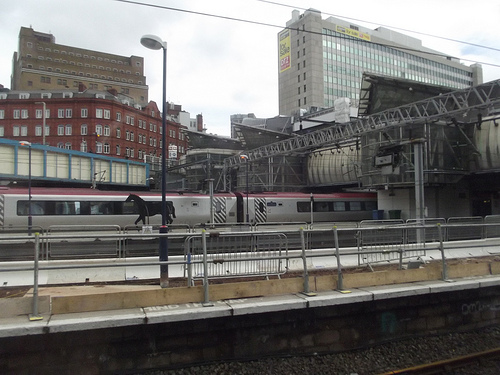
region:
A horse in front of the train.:
[123, 186, 183, 232]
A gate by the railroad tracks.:
[181, 231, 293, 289]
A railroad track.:
[270, 327, 497, 372]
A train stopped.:
[5, 184, 381, 229]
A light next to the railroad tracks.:
[120, 27, 206, 306]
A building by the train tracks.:
[5, 130, 157, 193]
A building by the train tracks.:
[10, 16, 158, 93]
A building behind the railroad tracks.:
[270, 17, 497, 147]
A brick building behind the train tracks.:
[2, 84, 211, 174]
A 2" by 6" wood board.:
[50, 266, 316, 317]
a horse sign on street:
[119, 178, 180, 226]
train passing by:
[3, 172, 390, 227]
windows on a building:
[25, 107, 103, 120]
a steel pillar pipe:
[399, 118, 436, 265]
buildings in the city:
[266, 6, 497, 134]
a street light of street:
[109, 22, 204, 294]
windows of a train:
[292, 185, 381, 218]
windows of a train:
[4, 187, 183, 222]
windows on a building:
[330, 40, 398, 72]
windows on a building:
[290, 20, 315, 113]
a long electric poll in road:
[135, 23, 191, 313]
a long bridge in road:
[43, 215, 493, 304]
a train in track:
[43, 175, 377, 227]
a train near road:
[23, 163, 390, 229]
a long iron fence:
[55, 231, 480, 328]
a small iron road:
[183, 222, 225, 305]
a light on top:
[129, 29, 188, 66]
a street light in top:
[133, 23, 167, 57]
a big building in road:
[16, 40, 178, 202]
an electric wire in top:
[128, 0, 498, 66]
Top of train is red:
[0, 179, 384, 198]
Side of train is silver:
[0, 196, 382, 234]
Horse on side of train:
[122, 194, 179, 228]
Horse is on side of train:
[120, 191, 177, 227]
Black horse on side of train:
[125, 191, 175, 226]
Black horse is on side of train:
[121, 193, 176, 230]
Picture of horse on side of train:
[123, 191, 178, 228]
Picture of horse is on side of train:
[120, 190, 177, 230]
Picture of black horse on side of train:
[122, 190, 175, 229]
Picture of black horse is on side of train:
[123, 190, 179, 227]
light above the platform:
[117, 25, 198, 270]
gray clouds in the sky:
[174, 26, 248, 111]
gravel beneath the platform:
[332, 313, 483, 373]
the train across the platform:
[3, 190, 397, 227]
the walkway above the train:
[221, 122, 498, 204]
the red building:
[12, 91, 200, 177]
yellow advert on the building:
[270, 28, 293, 73]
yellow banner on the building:
[327, 23, 379, 41]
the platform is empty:
[2, 235, 498, 285]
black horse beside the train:
[120, 190, 178, 229]